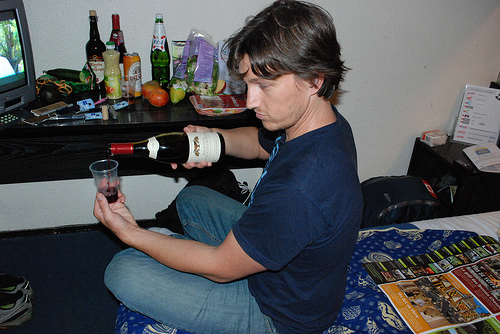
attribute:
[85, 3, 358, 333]
man — light, sitted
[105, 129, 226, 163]
bottle — black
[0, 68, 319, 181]
table — black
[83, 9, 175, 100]
bottles — glass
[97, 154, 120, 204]
wine — flowing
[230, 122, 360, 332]
shirt — blue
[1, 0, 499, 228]
wall — white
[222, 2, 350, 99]
hair — short